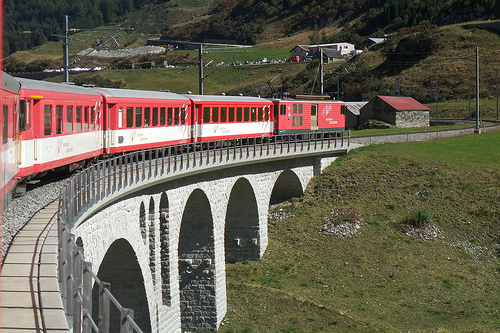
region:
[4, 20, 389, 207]
a train on a track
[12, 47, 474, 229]
a train on a bridge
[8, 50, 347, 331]
a train on a brick bridge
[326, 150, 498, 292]
a green grass field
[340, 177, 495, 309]
a field of green grass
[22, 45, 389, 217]
a red train on a track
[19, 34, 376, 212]
a track with a train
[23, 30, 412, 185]
a red train with red cars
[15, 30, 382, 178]
a passenger train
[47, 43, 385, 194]
a red passenger train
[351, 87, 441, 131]
little stone house with red roof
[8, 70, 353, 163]
red passenger train on a bridge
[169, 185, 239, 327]
stone arch way under a train bridge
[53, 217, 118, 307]
fencing on the side of a train bridge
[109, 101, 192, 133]
tinted passenger windows on a train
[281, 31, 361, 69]
white house overlooking a train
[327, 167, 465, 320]
grassy hill near a train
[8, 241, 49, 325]
power line shadows on the cement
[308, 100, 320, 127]
door on a red train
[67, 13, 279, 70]
telephone and power lines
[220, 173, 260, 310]
a white stone archway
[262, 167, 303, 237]
a white stone archway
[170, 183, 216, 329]
a white stone archway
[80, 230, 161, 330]
a white stone archway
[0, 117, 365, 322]
a train overpass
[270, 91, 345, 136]
a red train caboose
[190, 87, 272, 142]
white and red train car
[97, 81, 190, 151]
white and red train car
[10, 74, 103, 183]
white and red train car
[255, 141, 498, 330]
a rocky green hillside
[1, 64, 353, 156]
Long red train with five cabs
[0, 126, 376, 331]
Railroad track on top of a brick bridge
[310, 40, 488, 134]
Tall, wooden power lines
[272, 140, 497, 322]
Sloping green hill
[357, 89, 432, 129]
Red roofed barn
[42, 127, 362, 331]
Long metal railings on top of bridge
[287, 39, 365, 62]
Small, wooden house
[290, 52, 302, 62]
Red metal barrel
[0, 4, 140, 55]
Forest filled with pine trees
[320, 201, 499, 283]
Rocky landscape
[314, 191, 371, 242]
cluster of white rocks on grass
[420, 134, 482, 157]
bright green grass on side of track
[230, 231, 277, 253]
white rocks under white column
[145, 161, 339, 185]
shadow cast under the railing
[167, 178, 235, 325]
large dome white columns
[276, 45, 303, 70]
bright red object on hill side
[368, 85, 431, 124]
large stone building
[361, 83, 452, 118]
red slanted roof on building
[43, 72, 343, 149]
red and white train on the track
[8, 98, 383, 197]
curved edge of train track